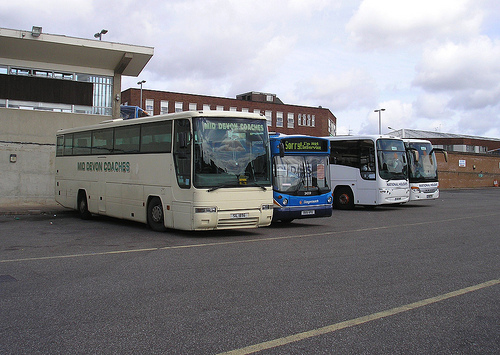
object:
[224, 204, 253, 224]
licence plate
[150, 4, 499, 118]
sky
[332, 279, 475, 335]
line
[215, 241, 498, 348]
road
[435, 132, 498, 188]
building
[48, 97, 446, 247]
buses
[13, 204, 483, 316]
parking lot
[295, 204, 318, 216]
licence plate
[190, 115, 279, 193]
windshield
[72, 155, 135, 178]
name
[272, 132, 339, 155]
digital window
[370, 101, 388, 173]
street lamp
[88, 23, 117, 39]
lights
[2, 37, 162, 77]
roof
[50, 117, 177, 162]
window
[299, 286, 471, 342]
line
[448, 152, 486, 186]
wall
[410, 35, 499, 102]
clouds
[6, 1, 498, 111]
sky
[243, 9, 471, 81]
clouds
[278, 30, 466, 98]
sky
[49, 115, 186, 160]
windows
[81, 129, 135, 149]
window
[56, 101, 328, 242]
vehicle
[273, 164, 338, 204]
window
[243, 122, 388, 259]
vehicle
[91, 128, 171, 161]
window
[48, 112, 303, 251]
bus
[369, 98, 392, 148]
light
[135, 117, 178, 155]
window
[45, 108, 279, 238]
vehicle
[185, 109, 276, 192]
window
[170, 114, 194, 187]
window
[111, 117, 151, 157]
window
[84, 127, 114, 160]
window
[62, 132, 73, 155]
window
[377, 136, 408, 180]
window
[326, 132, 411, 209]
vehicle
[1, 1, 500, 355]
daytime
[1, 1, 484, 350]
scene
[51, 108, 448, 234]
row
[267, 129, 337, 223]
bus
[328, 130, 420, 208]
bus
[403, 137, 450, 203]
bus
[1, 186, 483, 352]
street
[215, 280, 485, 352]
line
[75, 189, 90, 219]
tire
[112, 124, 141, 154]
window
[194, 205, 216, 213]
headlight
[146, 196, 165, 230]
tire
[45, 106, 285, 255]
bus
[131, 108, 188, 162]
window